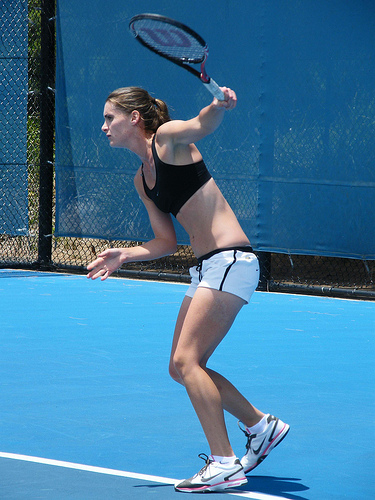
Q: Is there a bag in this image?
A: No, there are no bags.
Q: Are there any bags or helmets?
A: No, there are no bags or helmets.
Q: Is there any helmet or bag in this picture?
A: No, there are no bags or helmets.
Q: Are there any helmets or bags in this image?
A: No, there are no bags or helmets.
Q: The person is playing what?
A: The person is playing tennis.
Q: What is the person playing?
A: The person is playing tennis.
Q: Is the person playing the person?
A: Yes, the person is playing tennis.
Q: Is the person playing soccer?
A: No, the person is playing tennis.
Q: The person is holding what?
A: The person is holding the tennis racket.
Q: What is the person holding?
A: The person is holding the tennis racket.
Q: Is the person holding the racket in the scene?
A: Yes, the person is holding the racket.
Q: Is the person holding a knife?
A: No, the person is holding the racket.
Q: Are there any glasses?
A: No, there are no glasses.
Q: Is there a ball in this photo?
A: No, there are no balls.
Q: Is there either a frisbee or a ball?
A: No, there are no balls or frisbees.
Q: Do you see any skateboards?
A: No, there are no skateboards.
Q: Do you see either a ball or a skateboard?
A: No, there are no skateboards or balls.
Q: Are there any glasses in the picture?
A: No, there are no glasses.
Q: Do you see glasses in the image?
A: No, there are no glasses.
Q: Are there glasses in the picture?
A: No, there are no glasses.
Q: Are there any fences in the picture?
A: Yes, there is a fence.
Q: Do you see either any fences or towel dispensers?
A: Yes, there is a fence.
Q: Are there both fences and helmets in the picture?
A: No, there is a fence but no helmets.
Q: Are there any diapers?
A: No, there are no diapers.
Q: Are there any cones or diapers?
A: No, there are no diapers or cones.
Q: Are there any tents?
A: No, there are no tents.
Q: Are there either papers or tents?
A: No, there are no tents or papers.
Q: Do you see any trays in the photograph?
A: No, there are no trays.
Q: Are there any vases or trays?
A: No, there are no trays or vases.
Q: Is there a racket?
A: Yes, there is a racket.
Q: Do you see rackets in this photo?
A: Yes, there is a racket.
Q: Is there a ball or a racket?
A: Yes, there is a racket.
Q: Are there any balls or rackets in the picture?
A: Yes, there is a racket.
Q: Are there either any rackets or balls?
A: Yes, there is a racket.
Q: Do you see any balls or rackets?
A: Yes, there is a racket.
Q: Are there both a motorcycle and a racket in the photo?
A: No, there is a racket but no motorcycles.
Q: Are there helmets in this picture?
A: No, there are no helmets.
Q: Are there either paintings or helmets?
A: No, there are no helmets or paintings.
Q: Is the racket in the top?
A: Yes, the racket is in the top of the image.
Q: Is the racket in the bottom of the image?
A: No, the racket is in the top of the image.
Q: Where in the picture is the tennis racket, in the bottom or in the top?
A: The tennis racket is in the top of the image.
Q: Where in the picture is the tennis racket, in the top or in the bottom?
A: The tennis racket is in the top of the image.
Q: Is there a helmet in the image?
A: No, there are no helmets.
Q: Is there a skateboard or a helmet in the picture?
A: No, there are no helmets or skateboards.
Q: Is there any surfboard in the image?
A: No, there are no surfboards.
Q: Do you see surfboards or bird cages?
A: No, there are no surfboards or bird cages.